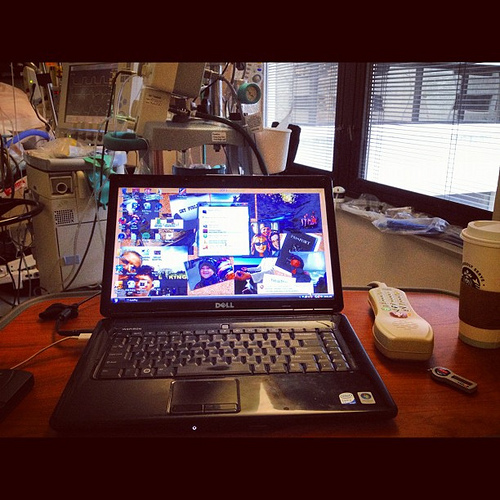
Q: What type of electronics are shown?
A: Laptop.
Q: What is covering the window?
A: Blinds.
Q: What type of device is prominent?
A: Laptop.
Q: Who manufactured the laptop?
A: Dell.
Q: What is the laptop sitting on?
A: Desk.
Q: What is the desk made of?
A: Wood.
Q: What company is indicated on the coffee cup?
A: Starbucks.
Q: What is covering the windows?
A: Blinds.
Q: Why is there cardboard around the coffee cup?
A: Protect hands.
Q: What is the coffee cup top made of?
A: Plastic.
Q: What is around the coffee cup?
A: Cardboard.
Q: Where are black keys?
A: On laptop keyboard.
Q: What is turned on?
A: Laptop screen.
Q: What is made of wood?
A: Table.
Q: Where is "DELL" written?
A: On the laptop.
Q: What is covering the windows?
A: Blinds.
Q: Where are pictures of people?
A: On laptop screen.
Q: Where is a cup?
A: On the table.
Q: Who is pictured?
A: No one.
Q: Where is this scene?
A: Hospital room.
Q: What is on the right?
A: Window.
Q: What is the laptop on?
A: Desk.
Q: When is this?
A: During the day.